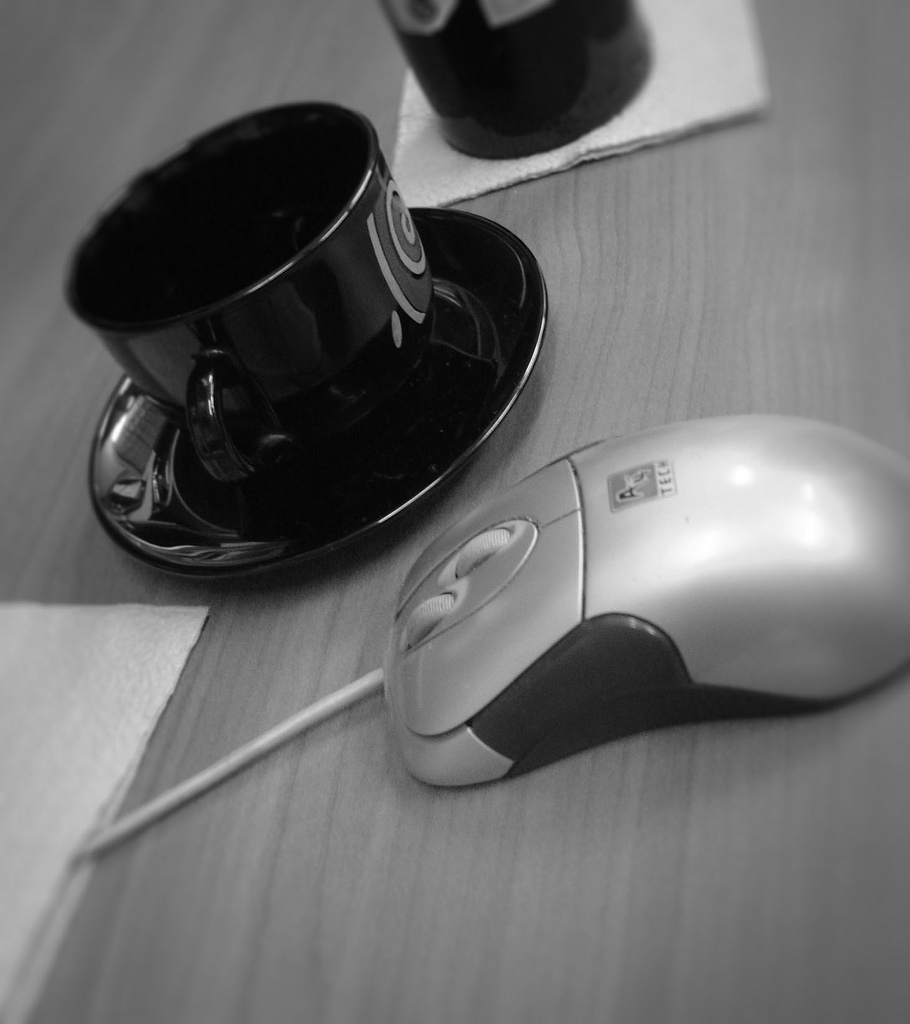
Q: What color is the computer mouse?
A: Gray.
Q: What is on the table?
A: A mouse.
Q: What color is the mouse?
A: Silver and black.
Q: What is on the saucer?
A: A cup.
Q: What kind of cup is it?
A: Teacup.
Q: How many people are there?
A: None.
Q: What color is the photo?
A: Black and white.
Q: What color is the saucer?
A: Black.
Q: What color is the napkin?
A: White.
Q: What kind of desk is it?
A: Wooden.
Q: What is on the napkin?
A: A black object.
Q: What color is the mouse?
A: Silver and black.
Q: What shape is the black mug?
A: Round.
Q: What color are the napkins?
A: White.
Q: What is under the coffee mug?
A: A plate.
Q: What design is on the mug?
A: A circular design.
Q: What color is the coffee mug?
A: Black.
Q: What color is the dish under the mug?
A: Black.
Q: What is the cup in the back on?
A: A cloth.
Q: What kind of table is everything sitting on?
A: Wood.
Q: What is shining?
A: The rooms reflection.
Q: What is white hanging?
A: Mouse cord.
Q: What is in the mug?
A: Its empty.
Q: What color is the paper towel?
A: White.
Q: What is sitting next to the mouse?
A: Black cup and saucer.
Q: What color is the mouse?
A: Silver.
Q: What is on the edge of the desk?
A: Edge of paper towel.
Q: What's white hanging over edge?
A: Cord of the mouse.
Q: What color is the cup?
A: Black.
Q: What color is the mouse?
A: Silver and black.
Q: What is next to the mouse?
A: A cup.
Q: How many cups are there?
A: Two.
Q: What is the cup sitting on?
A: A plate.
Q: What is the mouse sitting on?
A: Table.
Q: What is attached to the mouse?
A: A white chord.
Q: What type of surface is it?
A: Wooden.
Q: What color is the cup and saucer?
A: They are black.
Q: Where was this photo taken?
A: It was taken inside.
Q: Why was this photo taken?
A: TO show the cup and mouse.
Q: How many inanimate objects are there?
A: 4.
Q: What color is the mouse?
A: Grey and black.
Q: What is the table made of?
A: Wood.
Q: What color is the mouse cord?
A: Grey.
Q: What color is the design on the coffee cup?
A: Grey.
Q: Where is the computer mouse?
A: On table.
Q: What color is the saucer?
A: Black.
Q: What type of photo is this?
A: Black and white.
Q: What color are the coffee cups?
A: Black.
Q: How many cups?
A: Two.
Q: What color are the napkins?
A: White.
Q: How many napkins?
A: Two.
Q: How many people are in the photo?
A: None.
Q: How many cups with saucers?
A: One.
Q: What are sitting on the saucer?
A: Black coffee cups.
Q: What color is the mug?
A: Black.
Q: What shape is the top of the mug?
A: Circle shaped.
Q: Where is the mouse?
A: On the table.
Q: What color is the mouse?
A: Silver and black.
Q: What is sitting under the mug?
A: A tissue.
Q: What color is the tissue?
A: White.